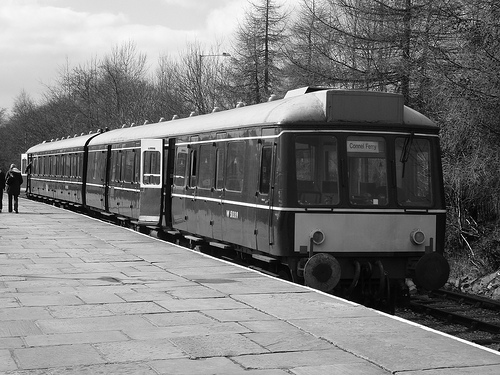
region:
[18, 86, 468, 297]
Very long train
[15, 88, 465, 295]
Very long train with lots of windows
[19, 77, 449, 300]
train consisting of two cars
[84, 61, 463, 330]
First train car of the train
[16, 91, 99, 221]
Second train car of the train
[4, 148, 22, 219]
person waiting on train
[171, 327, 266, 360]
cement block in the sidewalk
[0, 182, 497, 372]
sidewalk beside the train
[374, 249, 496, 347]
railroad track in front of the train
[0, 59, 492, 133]
wooded area behind the train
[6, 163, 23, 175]
this is a white hat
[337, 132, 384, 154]
this is a sign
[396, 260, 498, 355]
this is a train track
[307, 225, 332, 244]
the small right headlight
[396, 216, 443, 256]
the small left headlight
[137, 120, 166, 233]
an open train door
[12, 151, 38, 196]
the back train door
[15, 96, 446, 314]
this is a train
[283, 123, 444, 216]
this is the windshield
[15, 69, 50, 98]
this is the sky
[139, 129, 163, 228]
open door on a train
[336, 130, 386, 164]
sign on the front of a train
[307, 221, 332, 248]
head light on a train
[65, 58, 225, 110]
dead trees beside the train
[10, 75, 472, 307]
train at a train station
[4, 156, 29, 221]
person waiting for a train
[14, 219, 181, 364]
stone platform by a train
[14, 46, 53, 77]
grey overcast sky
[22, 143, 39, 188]
a person loading off of a train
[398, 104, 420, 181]
wiper on a train windshield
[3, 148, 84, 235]
Person standing on platform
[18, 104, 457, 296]
Train stopped at station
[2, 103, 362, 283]
Person standing near train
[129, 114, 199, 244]
Opened train door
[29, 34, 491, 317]
Train next to wooded area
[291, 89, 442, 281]
Sign on front of train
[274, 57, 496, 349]
Train on train tracks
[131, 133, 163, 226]
Door on side of train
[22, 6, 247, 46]
Clouds in sky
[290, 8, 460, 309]
Tree branches above stopped train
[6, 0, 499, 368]
black and white photograph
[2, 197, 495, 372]
grey stone tiles on platform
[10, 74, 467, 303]
grey and white train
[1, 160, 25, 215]
person wearing black on platform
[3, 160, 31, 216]
person wearing black coat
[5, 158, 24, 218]
person wearing black pants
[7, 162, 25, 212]
person wearing beige hat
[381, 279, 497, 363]
metal and iron train tracks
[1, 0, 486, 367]
outdoor daytime railroad scene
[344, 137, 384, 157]
white sign with black lettering